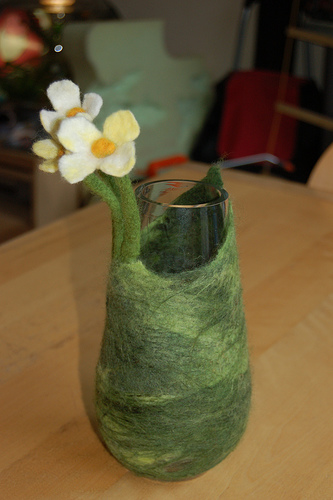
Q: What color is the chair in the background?
A: Red.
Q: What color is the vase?
A: Green.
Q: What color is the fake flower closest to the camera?
A: Yellow.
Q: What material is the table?
A: Wood.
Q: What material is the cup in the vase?
A: Glass.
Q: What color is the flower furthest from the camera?
A: White.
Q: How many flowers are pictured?
A: Three.